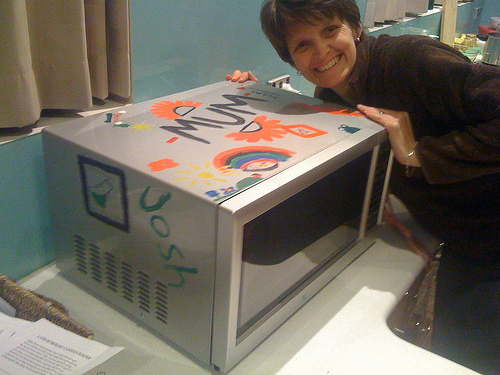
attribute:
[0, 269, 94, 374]
basket — wicker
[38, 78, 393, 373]
microwave — silver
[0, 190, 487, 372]
counter — white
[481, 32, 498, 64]
crockpot — silver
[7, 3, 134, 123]
curtains — brown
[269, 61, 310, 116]
plug — white, electrical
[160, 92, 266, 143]
mum — written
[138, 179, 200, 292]
name — green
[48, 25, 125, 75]
curtain — beige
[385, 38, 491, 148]
sweater — brown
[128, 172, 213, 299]
josh — green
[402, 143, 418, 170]
bracelet — silver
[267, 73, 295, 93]
outlet — silver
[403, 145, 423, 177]
bracelet — silver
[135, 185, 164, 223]
paint — green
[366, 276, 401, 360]
counter top — white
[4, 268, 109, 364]
basket — wicker